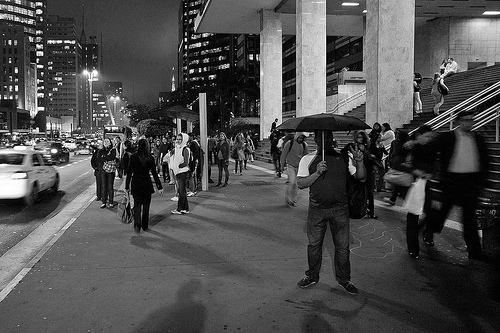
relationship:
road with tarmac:
[2, 144, 99, 296] [18, 229, 286, 319]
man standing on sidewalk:
[284, 129, 365, 294] [170, 223, 241, 331]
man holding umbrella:
[284, 129, 365, 294] [274, 114, 372, 172]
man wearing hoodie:
[278, 128, 310, 214] [279, 132, 307, 167]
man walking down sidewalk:
[278, 128, 310, 214] [224, 167, 484, 327]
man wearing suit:
[418, 109, 481, 272] [434, 131, 487, 213]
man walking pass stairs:
[418, 109, 481, 272] [450, 64, 494, 131]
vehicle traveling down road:
[23, 130, 76, 175] [42, 140, 107, 207]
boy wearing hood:
[167, 131, 197, 218] [174, 129, 192, 147]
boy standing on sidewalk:
[167, 131, 197, 218] [83, 237, 289, 319]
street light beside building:
[76, 65, 105, 85] [52, 30, 89, 133]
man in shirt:
[296, 129, 364, 296] [286, 144, 363, 214]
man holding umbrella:
[296, 129, 364, 296] [277, 112, 371, 162]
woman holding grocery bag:
[389, 113, 439, 270] [399, 170, 434, 222]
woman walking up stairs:
[428, 64, 451, 114] [241, 64, 496, 168]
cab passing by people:
[4, 127, 82, 229] [89, 129, 259, 240]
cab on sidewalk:
[4, 127, 82, 229] [74, 244, 293, 325]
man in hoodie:
[296, 129, 364, 296] [281, 130, 308, 172]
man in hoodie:
[279, 132, 310, 207] [166, 131, 197, 177]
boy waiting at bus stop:
[169, 131, 198, 214] [71, 78, 227, 283]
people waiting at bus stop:
[121, 137, 161, 233] [71, 78, 227, 283]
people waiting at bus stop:
[215, 131, 230, 186] [71, 78, 227, 283]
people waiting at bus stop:
[102, 137, 112, 207] [71, 78, 227, 283]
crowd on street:
[90, 129, 256, 235] [72, 176, 258, 284]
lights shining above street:
[68, 49, 107, 113] [49, 187, 123, 327]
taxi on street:
[2, 141, 62, 211] [2, 138, 100, 268]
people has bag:
[97, 138, 116, 209] [91, 146, 121, 185]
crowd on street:
[97, 122, 238, 179] [22, 120, 115, 190]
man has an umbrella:
[296, 129, 364, 296] [274, 95, 376, 155]